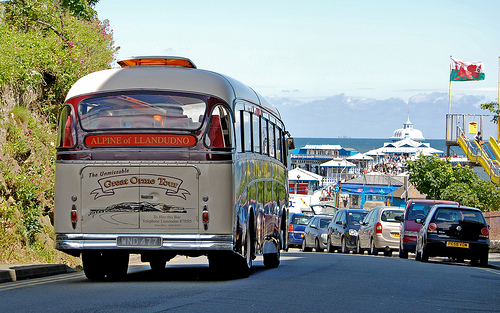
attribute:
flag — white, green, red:
[448, 56, 494, 92]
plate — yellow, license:
[440, 235, 480, 252]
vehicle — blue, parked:
[286, 210, 314, 253]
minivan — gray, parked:
[354, 201, 402, 256]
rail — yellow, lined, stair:
[445, 106, 498, 188]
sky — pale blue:
[94, 3, 498, 143]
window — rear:
[61, 94, 225, 157]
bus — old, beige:
[47, 51, 296, 284]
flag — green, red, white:
[444, 55, 494, 83]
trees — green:
[5, 4, 120, 272]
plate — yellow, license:
[441, 235, 471, 251]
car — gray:
[353, 199, 407, 260]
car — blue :
[282, 207, 315, 250]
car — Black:
[416, 203, 496, 260]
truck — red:
[394, 195, 468, 264]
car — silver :
[354, 193, 405, 253]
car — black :
[322, 207, 370, 254]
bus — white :
[45, 43, 319, 279]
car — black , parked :
[411, 203, 492, 271]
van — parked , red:
[394, 194, 464, 254]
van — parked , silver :
[355, 203, 408, 253]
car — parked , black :
[320, 203, 374, 253]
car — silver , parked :
[297, 209, 334, 253]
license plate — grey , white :
[120, 229, 160, 252]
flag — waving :
[443, 46, 493, 96]